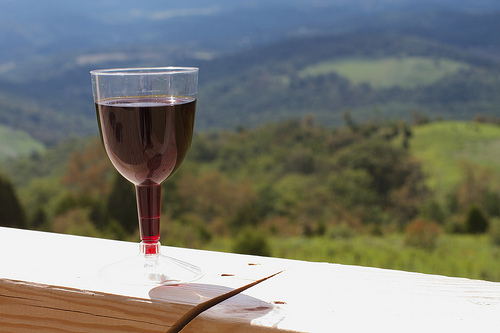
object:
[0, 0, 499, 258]
trees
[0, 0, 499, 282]
background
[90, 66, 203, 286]
glass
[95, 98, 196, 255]
wine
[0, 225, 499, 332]
sill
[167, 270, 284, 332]
crack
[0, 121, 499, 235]
hill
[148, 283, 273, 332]
shadow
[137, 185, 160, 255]
handle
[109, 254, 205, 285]
base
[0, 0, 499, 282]
grass